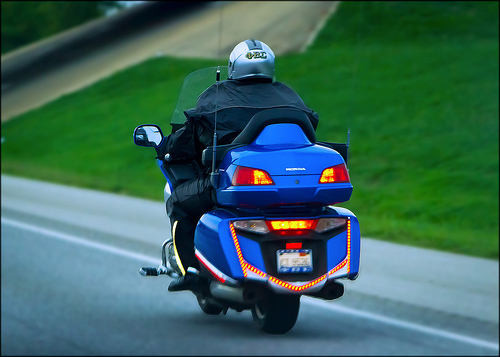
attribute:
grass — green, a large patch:
[0, 0, 498, 260]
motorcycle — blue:
[126, 107, 372, 337]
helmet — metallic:
[222, 37, 278, 75]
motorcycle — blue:
[150, 108, 379, 300]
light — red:
[242, 161, 270, 178]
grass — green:
[0, 3, 499, 287]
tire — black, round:
[239, 282, 306, 336]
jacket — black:
[148, 27, 356, 294]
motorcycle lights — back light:
[217, 158, 288, 201]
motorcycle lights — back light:
[308, 156, 368, 187]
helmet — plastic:
[222, 35, 282, 85]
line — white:
[6, 209, 127, 268]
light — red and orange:
[228, 165, 273, 185]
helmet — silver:
[188, 17, 309, 89]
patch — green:
[2, 1, 497, 259]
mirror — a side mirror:
[133, 125, 162, 147]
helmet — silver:
[227, 38, 275, 80]